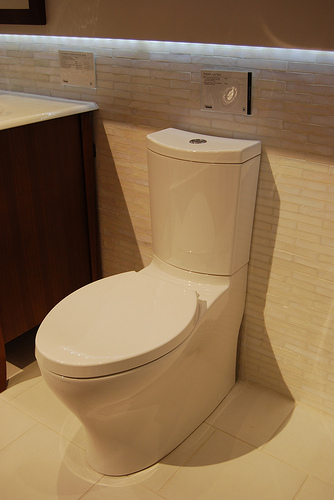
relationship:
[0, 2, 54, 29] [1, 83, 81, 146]
frame above counter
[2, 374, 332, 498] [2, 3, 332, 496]
floor in bathroom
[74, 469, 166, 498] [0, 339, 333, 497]
tile in floor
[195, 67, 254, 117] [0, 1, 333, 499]
sign above bathroom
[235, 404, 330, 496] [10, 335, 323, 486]
tile in floor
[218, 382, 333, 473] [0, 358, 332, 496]
tile on floor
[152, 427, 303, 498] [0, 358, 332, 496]
tile on floor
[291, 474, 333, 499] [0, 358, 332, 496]
tile on floor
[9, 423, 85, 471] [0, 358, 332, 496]
tile on floor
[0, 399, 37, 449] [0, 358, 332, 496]
tile on floor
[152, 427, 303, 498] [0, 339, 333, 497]
tile on floor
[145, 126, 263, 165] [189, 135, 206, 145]
lid with button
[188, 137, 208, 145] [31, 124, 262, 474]
button on toilet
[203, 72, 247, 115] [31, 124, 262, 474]
sign above toilet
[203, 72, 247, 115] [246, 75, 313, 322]
sign on wall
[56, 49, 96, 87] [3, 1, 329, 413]
sign on wall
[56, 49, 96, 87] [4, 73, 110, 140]
sign above counter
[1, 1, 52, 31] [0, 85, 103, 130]
picture above counter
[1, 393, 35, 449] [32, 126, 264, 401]
tile next to toilet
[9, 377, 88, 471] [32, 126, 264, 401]
tile next to toilet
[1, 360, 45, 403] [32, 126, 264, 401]
tile next to toilet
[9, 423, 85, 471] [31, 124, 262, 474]
tile next to toilet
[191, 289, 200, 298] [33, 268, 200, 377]
hinge on lid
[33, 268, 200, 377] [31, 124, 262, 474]
lid on toilet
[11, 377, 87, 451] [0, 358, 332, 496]
tile in floor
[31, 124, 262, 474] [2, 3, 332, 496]
toilet in bathroom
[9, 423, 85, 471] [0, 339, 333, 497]
tile on floor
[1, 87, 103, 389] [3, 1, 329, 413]
sink against wall